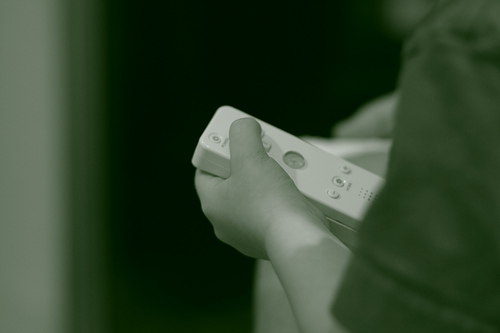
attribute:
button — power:
[203, 125, 225, 151]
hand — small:
[168, 84, 390, 275]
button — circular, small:
[209, 133, 222, 142]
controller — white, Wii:
[187, 110, 392, 217]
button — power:
[208, 130, 221, 142]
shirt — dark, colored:
[376, 34, 471, 303]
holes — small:
[352, 182, 377, 201]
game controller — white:
[193, 99, 392, 242]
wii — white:
[191, 102, 385, 234]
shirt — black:
[365, 45, 487, 325]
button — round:
[209, 131, 222, 145]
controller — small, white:
[214, 87, 380, 245]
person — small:
[277, 32, 477, 329]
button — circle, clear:
[282, 150, 307, 171]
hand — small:
[193, 114, 340, 268]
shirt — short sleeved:
[325, 50, 496, 333]